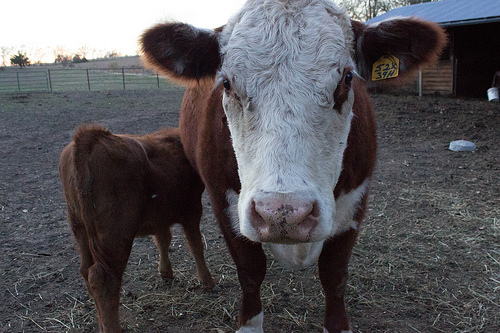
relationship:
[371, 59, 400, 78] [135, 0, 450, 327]
tag on cow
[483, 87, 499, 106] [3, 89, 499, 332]
bucket on ground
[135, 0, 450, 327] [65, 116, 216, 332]
cow has calf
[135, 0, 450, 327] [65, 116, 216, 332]
cow feeds calf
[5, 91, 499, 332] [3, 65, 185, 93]
pen has fence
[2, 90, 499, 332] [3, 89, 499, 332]
hay on ground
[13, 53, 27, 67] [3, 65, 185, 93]
tree behind fence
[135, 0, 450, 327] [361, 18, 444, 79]
cow has ear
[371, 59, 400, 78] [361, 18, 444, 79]
tag on ear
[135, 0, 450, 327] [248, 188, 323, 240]
cow has nose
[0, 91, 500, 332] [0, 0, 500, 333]
hay laying in barnyard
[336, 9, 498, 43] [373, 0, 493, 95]
roof of building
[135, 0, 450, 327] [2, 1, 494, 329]
cow in a farm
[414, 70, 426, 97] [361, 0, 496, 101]
post on side of barn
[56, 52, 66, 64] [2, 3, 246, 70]
bushes sitting in background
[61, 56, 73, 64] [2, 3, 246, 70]
bushes sitting in background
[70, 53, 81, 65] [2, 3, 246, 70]
bushes sitting in background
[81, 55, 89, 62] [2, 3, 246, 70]
bushes sitting in background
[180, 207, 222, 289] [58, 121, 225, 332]
leg of baby cow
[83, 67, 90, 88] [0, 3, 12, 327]
fence post from left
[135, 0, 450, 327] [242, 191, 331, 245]
cow has nose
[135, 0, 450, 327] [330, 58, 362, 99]
cow has eye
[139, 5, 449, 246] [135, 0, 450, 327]
head of cow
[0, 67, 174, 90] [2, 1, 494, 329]
fence of farm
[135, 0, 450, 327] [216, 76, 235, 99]
cow has eye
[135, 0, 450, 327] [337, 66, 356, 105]
cow has eye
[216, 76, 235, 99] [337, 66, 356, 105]
eye far apart from eye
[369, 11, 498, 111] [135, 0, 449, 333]
ranch behind cow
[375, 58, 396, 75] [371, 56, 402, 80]
5239h written on tag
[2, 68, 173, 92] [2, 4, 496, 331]
fence around ranch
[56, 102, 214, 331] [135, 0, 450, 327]
baby cow nursing from cow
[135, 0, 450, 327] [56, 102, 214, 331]
cow nursing baby cow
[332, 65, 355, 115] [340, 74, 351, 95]
ring encircles eye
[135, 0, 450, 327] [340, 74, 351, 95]
cow has eye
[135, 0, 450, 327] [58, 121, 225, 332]
cow and baby cow